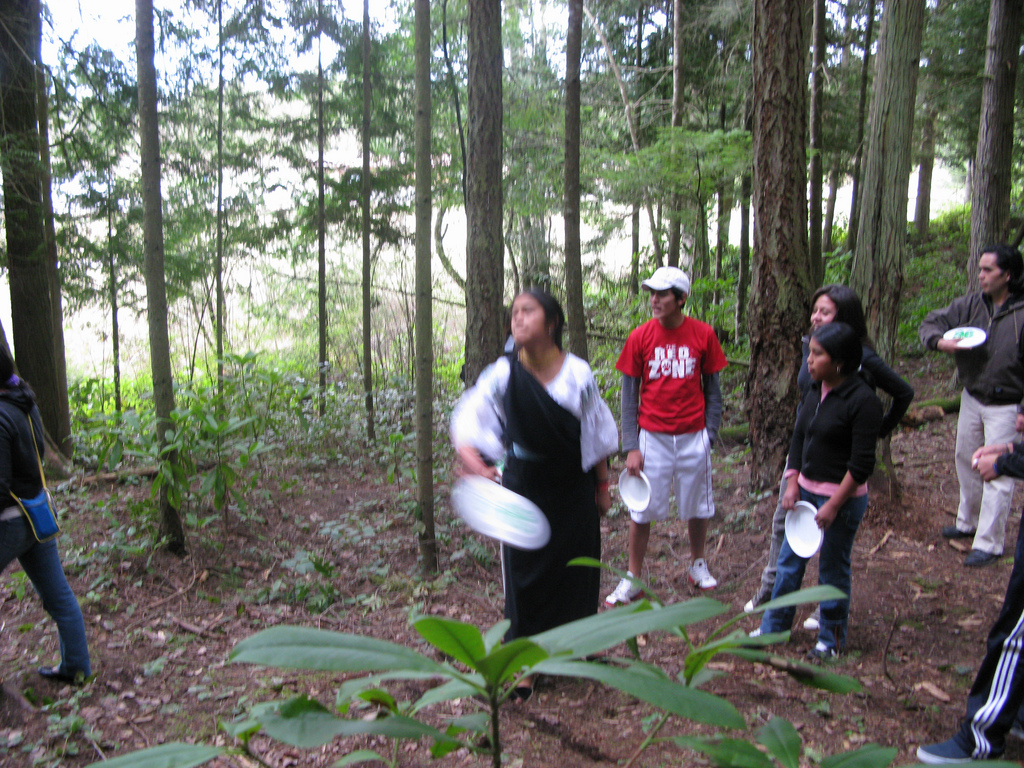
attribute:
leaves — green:
[529, 623, 749, 735]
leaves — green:
[325, 45, 430, 284]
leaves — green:
[589, 95, 758, 219]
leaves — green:
[58, 30, 160, 313]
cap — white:
[631, 263, 701, 296]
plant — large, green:
[534, 587, 705, 671]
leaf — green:
[716, 128, 751, 166]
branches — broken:
[5, 350, 1021, 766]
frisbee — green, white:
[416, 466, 566, 574]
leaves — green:
[232, 598, 545, 723]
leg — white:
[955, 541, 1022, 751]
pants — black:
[948, 574, 1021, 753]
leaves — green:
[525, 549, 856, 720]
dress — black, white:
[427, 344, 631, 626]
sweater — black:
[781, 370, 879, 491]